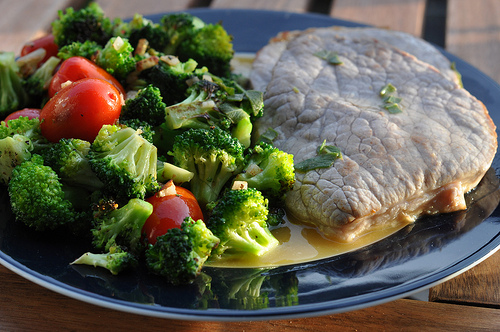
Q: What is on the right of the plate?
A: A piece of meat.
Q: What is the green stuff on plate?
A: Broccoli.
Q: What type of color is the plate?
A: Blue.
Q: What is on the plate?
A: Food.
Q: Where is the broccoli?
A: On the plate.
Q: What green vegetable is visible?
A: Broccoli.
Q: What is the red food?
A: Tomato.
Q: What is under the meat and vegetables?
A: Sauce.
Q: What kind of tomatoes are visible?
A: Grape tomatoes.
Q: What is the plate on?
A: A wood table.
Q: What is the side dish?
A: Salad.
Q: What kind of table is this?
A: Wooden.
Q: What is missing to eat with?
A: Utensils.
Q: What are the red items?
A: Tomatoes.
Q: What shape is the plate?
A: Round.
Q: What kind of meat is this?
A: Pork.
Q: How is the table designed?
A: Slotted.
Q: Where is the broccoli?
A: On the plate.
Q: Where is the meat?
A: On the plate.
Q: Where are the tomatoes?
A: Mixed in the broccoli.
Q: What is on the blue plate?
A: Meat and vegetables.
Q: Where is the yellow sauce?
A: Under the meat and vegetables.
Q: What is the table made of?
A: Wood.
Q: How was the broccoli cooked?
A: Steamed.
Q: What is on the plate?
A: Food.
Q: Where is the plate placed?
A: Table.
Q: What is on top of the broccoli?
A: Tomato.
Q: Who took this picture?
A: A person.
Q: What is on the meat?
A: Green onion.